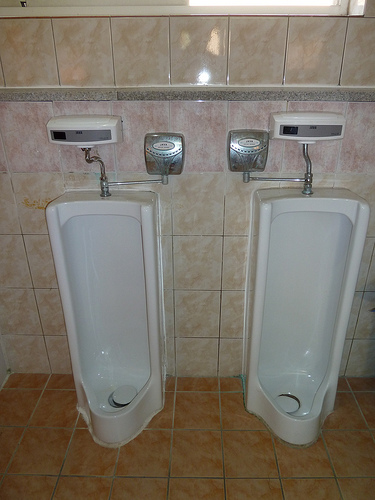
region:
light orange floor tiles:
[160, 423, 244, 495]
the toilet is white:
[29, 151, 221, 424]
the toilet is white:
[35, 212, 162, 409]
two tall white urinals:
[18, 174, 368, 464]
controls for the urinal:
[187, 79, 358, 198]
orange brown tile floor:
[162, 421, 272, 497]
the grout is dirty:
[145, 443, 215, 498]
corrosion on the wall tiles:
[17, 182, 90, 222]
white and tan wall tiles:
[152, 187, 252, 331]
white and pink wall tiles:
[159, 104, 242, 181]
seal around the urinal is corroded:
[219, 366, 309, 451]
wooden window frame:
[7, 4, 374, 56]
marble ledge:
[10, 84, 374, 109]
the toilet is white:
[63, 260, 214, 431]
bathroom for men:
[5, 2, 373, 495]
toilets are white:
[40, 175, 362, 467]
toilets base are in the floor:
[37, 176, 373, 462]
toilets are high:
[38, 181, 179, 460]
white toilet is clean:
[40, 183, 167, 451]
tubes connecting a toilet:
[67, 147, 191, 193]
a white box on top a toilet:
[36, 110, 131, 153]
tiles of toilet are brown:
[1, 371, 373, 498]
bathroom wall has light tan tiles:
[3, 1, 371, 377]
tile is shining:
[138, 17, 263, 108]